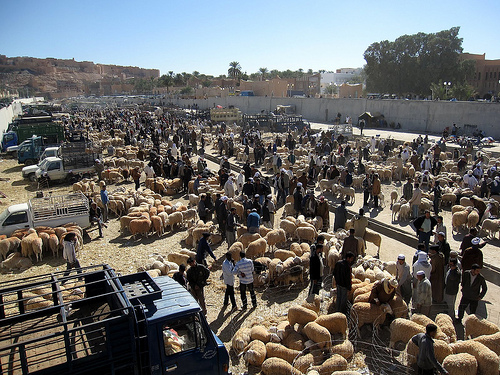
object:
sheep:
[114, 191, 196, 249]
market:
[0, 98, 500, 375]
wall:
[425, 102, 499, 135]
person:
[222, 252, 245, 307]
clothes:
[162, 328, 184, 357]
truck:
[1, 263, 232, 374]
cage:
[30, 190, 90, 222]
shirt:
[412, 280, 433, 308]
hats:
[397, 253, 430, 301]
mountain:
[66, 59, 103, 95]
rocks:
[15, 56, 28, 68]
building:
[338, 83, 363, 99]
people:
[196, 179, 207, 205]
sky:
[11, 4, 70, 56]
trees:
[364, 40, 397, 94]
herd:
[231, 324, 251, 359]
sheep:
[242, 338, 267, 367]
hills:
[0, 56, 56, 99]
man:
[195, 231, 219, 267]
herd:
[243, 237, 266, 260]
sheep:
[0, 236, 20, 260]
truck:
[0, 122, 65, 151]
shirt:
[232, 257, 255, 284]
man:
[332, 253, 355, 316]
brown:
[348, 237, 355, 254]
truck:
[35, 152, 96, 183]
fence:
[0, 105, 20, 148]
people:
[372, 174, 381, 208]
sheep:
[408, 165, 415, 179]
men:
[415, 270, 433, 317]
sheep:
[349, 302, 392, 333]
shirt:
[224, 180, 238, 197]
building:
[241, 76, 288, 97]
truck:
[0, 190, 91, 238]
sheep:
[304, 322, 333, 351]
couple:
[222, 251, 258, 310]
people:
[428, 181, 442, 216]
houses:
[339, 80, 367, 99]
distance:
[4, 63, 102, 90]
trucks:
[17, 136, 60, 167]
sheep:
[243, 237, 269, 259]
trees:
[228, 61, 243, 78]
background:
[199, 13, 391, 118]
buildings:
[289, 73, 309, 97]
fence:
[246, 96, 270, 117]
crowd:
[99, 184, 110, 225]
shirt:
[247, 212, 261, 227]